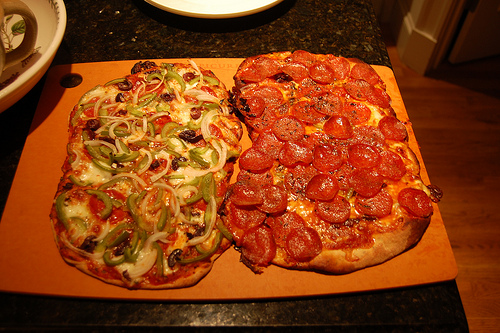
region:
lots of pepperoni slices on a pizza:
[245, 50, 418, 256]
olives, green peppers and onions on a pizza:
[86, 48, 223, 287]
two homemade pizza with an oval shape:
[69, 42, 456, 313]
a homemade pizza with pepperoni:
[238, 45, 445, 290]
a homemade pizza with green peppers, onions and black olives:
[78, 53, 228, 298]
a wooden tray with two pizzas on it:
[12, 52, 449, 292]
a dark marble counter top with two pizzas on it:
[80, 5, 450, 329]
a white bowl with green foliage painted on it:
[1, 0, 68, 90]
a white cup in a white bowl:
[2, 4, 69, 90]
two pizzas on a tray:
[78, 58, 432, 300]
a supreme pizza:
[72, 64, 215, 291]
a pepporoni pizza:
[231, 51, 428, 303]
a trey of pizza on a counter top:
[41, 83, 343, 328]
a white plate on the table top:
[157, 0, 285, 10]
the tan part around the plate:
[168, 9, 263, 29]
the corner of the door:
[408, 7, 494, 47]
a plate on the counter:
[10, 1, 72, 73]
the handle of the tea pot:
[12, 6, 42, 54]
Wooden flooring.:
[377, 19, 498, 331]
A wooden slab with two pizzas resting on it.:
[1, 49, 457, 301]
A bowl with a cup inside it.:
[0, 0, 67, 113]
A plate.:
[142, 0, 286, 18]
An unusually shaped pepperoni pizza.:
[219, 50, 443, 275]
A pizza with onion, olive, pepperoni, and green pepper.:
[49, 60, 244, 290]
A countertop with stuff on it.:
[0, 0, 470, 332]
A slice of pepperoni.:
[284, 226, 321, 262]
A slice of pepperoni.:
[325, 115, 354, 141]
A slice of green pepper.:
[84, 187, 112, 218]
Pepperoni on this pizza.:
[281, 85, 375, 167]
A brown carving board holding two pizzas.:
[76, 73, 381, 321]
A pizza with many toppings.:
[61, 80, 211, 256]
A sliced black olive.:
[86, 117, 103, 132]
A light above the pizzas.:
[122, 7, 347, 34]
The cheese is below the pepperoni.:
[261, 72, 379, 242]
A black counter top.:
[105, 292, 461, 327]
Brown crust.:
[301, 221, 428, 265]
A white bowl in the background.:
[8, 6, 131, 98]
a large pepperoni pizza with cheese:
[230, 54, 445, 276]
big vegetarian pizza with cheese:
[56, 62, 246, 287]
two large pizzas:
[47, 52, 411, 280]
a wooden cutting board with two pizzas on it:
[0, 55, 453, 296]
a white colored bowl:
[1, 0, 70, 112]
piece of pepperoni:
[238, 219, 275, 272]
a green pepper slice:
[81, 187, 113, 223]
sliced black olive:
[179, 125, 201, 141]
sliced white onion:
[108, 167, 154, 192]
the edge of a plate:
[138, 0, 300, 25]